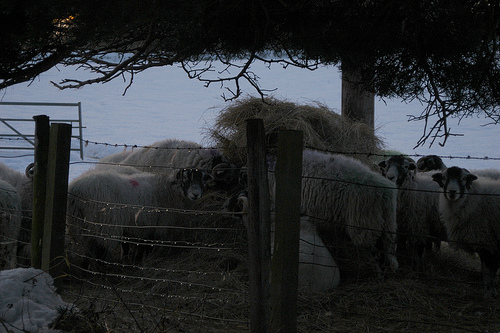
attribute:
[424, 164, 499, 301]
sheep — black, white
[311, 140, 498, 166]
wire — barbed 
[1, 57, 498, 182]
snow — white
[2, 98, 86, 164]
gate — silver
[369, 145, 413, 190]
head — black and white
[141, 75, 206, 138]
blue water — light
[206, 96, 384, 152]
straw — light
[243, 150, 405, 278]
sheep — White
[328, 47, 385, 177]
post — brown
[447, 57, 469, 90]
tree — green 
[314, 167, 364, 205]
hair — white 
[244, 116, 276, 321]
post — wooden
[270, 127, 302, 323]
post — wooden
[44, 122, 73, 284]
post — wooden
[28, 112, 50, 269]
post — wooden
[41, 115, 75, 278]
post — wooden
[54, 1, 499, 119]
leaves — green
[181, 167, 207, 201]
face — black, white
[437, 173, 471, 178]
ears — black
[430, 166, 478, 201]
head — turned 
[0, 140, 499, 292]
sheep — behind 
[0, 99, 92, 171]
gate — metal 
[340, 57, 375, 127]
trunk — light brown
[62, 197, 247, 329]
fence — silver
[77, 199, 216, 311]
wire fence — long, barbed